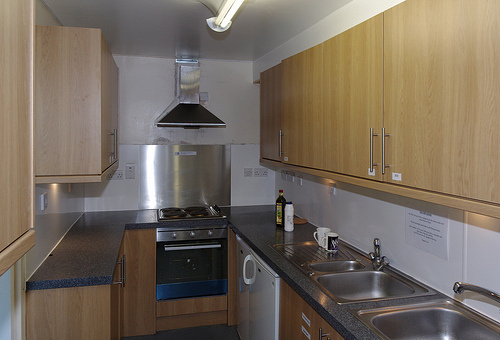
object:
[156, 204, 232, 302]
stove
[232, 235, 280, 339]
dishwasher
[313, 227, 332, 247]
mug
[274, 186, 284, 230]
bottle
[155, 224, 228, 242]
control panel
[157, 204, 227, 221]
stove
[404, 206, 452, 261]
paper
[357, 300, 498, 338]
sink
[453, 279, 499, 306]
faucet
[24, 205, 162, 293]
counter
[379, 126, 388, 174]
handle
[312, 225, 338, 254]
mug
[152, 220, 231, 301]
oven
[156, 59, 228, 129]
exhaust hood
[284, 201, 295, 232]
bottle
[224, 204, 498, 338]
counter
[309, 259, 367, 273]
sink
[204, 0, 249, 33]
light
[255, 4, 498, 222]
cabinets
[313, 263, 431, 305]
sink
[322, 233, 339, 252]
cups